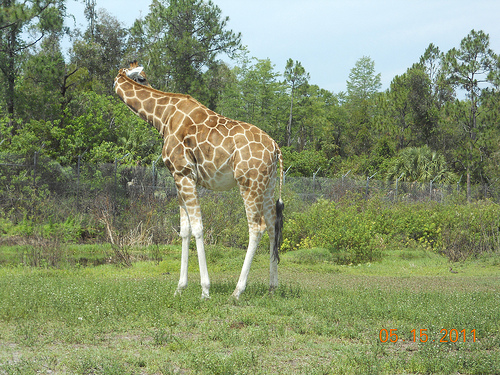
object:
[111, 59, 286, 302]
giraffe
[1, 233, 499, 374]
grass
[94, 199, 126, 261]
sticks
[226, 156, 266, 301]
giraffe's legs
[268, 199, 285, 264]
hair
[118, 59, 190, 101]
hair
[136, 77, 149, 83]
eyelashes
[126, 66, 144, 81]
ear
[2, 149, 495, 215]
fencing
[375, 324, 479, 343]
date stamp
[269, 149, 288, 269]
long tail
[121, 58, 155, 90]
giraffe's head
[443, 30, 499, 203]
tree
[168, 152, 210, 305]
long legs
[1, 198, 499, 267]
bushes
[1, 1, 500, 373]
giraffe's habitat